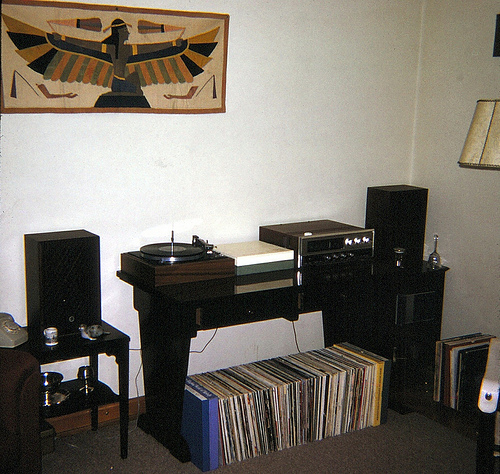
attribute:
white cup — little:
[42, 323, 59, 345]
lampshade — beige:
[456, 97, 498, 169]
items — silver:
[48, 364, 113, 414]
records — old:
[183, 345, 391, 472]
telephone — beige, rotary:
[1, 309, 33, 353]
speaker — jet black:
[23, 228, 103, 344]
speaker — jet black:
[365, 182, 428, 269]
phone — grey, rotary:
[1, 311, 27, 347]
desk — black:
[116, 249, 449, 464]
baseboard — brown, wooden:
[45, 394, 148, 432]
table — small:
[8, 308, 144, 471]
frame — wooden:
[0, 0, 230, 117]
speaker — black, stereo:
[14, 216, 122, 360]